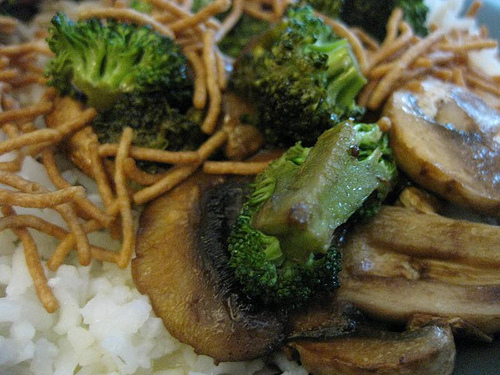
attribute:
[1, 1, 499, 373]
rice — white, cooked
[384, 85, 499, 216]
mushroom — sauteed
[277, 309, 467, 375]
mushroom — sauteed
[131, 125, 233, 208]
noodle — crispy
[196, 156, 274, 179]
noodle — crispy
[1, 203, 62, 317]
noodle — crispy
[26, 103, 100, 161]
noodle — crispy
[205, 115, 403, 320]
broccoli — cut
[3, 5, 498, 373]
fry — cooked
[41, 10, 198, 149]
broccoli — green, cooked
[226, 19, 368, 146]
broccoli — green, cooked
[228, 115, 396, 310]
broccoli — green, cooked, cut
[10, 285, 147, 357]
rice — cooked, fluffy, white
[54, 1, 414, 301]
broccoli — green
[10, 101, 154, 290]
topping — crunchy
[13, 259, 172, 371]
rice — white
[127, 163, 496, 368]
mushroom — sauteed, large, brown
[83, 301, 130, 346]
rice — curled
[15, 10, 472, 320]
meal — cooked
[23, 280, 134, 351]
rice — white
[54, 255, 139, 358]
rice — stir fry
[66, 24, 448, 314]
vegetable — stir fry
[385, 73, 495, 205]
mushroom — glistening, cut, brown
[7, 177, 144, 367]
rice — white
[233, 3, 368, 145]
broccoli — cut, small, green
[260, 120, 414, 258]
broccoli — stir fry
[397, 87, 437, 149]
mushrooms — stir fry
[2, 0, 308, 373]
rice — white, stir fry, cooked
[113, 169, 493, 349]
mushroom — tan, black, curved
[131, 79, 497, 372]
zucchini — cooked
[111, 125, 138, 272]
noodle — crispy, curved, short, fried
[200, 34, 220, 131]
noodle — curved, short, fried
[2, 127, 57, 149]
noodle — curved, short, fried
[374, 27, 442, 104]
noodle — curved, short, fried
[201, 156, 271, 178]
noodle — curved, short, fried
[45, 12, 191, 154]
broccoli — green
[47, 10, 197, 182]
broccoli — cut, small, green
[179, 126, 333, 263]
broccoli — green, tender, cooked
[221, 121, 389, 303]
broccoli floret — round, pin-like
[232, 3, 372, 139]
broccoli floret — cooked, round, pin-like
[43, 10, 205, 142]
broccoli floret — cooked, round, pin-like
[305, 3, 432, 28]
broccoli floret — round, pin-like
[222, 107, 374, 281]
broccoli — cooked, moist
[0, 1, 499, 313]
topping — crunchy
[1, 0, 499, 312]
noodles — brown, small